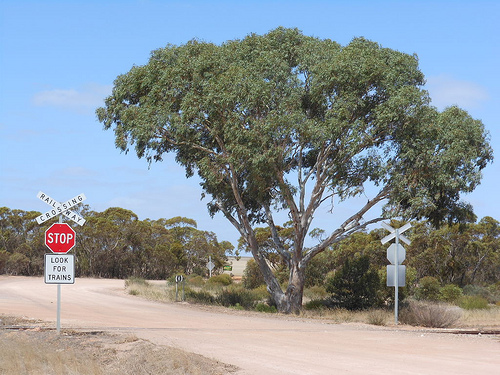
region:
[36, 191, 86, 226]
Rail Way Crossing on a large white X.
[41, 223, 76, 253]
A large red and white STOP sign.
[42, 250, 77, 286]
White and black sign that says LOOK FOR TRAINS.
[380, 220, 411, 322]
The back of a grey sign with a X on top.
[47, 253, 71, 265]
The black word LOOK.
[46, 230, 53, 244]
White S in STOP.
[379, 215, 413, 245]
Back of a X sign that is grey.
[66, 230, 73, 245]
Large white P in STOP.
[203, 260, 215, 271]
The back of a grey diamond shaped sign far down the road.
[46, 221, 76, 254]
Red and white STOP sign.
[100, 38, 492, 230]
The tree is leafy.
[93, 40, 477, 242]
The green is leafy.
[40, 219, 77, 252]
The sign is red.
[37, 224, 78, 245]
The letters are white.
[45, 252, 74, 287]
The sign is white.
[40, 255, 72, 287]
The lettering is black.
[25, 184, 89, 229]
The sign is white.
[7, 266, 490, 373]
the street is dirt.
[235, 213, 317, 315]
The trunk is brown.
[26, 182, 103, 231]
a white railway crossing sign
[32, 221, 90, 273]
a red STOP sign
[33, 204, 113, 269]
a red STOP sign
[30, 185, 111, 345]
signs on left side of road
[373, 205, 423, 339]
signs on right side of road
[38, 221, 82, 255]
a STOP sign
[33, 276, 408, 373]
the road is unpaved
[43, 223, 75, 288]
a white sign under a STOP sign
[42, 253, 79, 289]
white sign says "Look for trains"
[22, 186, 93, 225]
two signs of crossing railroad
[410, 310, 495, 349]
a shadow on the ground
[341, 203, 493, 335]
bushes behind a sign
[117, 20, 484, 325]
a big tree on side a road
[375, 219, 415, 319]
silver back of railroad crossing sign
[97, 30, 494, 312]
large tree with green foliage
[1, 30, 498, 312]
deciduous trees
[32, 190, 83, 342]
train crossing stop sign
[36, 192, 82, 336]
sign RAILWAY CROSSING STOP LOOK FOR TRAINS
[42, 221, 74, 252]
octagonal red and white STOP sign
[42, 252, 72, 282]
square black and white LOOK FOR TRAINS sign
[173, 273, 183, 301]
railway sign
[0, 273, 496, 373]
road crossing railway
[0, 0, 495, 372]
rural railway crossing